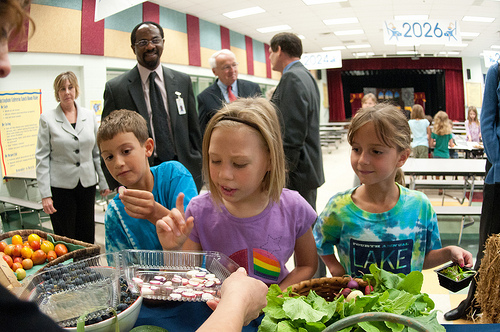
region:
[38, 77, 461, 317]
The kids are eating some vegetables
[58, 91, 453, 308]
The kids are getting something to eat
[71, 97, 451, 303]
The kids are getting free samples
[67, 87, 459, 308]
The kids are at their school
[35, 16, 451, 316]
The children are with some adults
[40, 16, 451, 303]
The children are enjoying themselves greatly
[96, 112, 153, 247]
The boy is holding something to eat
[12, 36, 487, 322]
The kids are enjoying a school function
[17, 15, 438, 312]
The teachers are watching the children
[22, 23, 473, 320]
The teachers are supervising the kids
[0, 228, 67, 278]
Unripe tomatoes in a basket.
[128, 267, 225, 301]
Radish slices in a plastic tray.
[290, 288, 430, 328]
Bright greens in a basket.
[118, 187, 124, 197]
Radish in a boy's hand.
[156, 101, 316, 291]
Little girl ready to try a radish slice.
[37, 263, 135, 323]
Blue berries in a white bowl.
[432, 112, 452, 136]
Little girl with long blond wavy hair.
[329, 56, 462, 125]
Red theater curtains in lunchroom.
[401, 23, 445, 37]
The year '2026' on lunchroom wall.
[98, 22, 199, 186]
Smiling man with name tag watching children.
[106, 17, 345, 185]
Three men in business suits.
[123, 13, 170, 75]
A man wearing glasses.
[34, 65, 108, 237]
A woman with blonde hair.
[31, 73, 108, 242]
Woman wearing a black skirt.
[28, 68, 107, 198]
Woman wearing a long sleeve jacket.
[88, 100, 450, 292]
Three children looking at vegetables.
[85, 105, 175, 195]
A boy with brown hair.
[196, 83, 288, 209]
A girl with headband in her hair.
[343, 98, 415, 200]
A girl with her hair in a ponytail.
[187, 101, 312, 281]
A girl wearing a purple shirt.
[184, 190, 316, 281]
The girl is wearing a purple shirt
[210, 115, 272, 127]
The girl is wearing a headband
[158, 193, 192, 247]
The right hand of the girl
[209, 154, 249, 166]
The eyes of the girl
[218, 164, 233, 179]
The nose of the girl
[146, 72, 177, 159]
The man is wearing a black tie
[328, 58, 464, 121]
A stage behind the children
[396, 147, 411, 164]
The left ear of the girl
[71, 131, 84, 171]
Buttons on the dress shirt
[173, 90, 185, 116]
A white badge on the suit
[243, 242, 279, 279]
rainbow flag on shirt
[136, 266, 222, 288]
small slices of radishes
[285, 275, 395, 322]
crisp green spinach leaves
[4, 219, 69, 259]
different color small tomatoes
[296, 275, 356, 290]
edge of brown basket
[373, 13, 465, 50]
large words on top of ceiling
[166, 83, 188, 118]
white name tag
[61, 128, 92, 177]
large black buttons on white jacket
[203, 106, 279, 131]
black head band on head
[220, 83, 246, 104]
red tie around neck